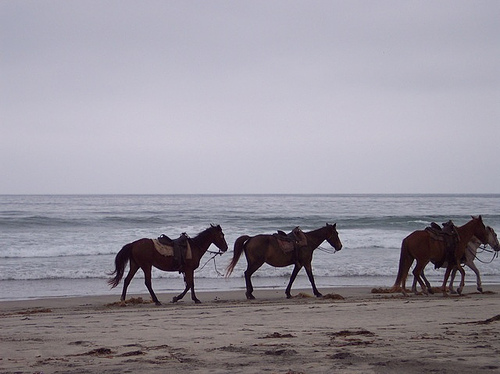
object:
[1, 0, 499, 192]
sky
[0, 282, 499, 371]
beach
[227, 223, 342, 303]
horse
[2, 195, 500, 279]
ocean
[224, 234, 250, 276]
tail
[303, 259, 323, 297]
leg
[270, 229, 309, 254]
saddle